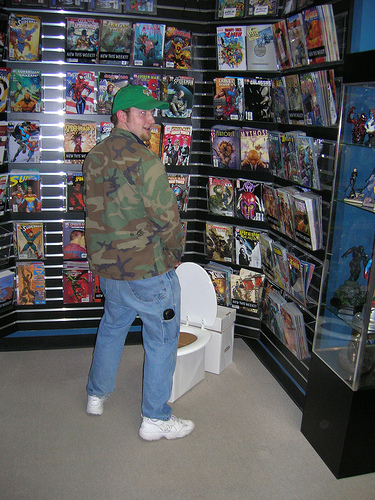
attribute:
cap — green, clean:
[106, 79, 174, 114]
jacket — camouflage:
[39, 125, 206, 275]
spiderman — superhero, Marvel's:
[61, 265, 98, 303]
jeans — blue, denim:
[92, 261, 172, 423]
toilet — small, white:
[155, 261, 256, 405]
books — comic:
[252, 22, 349, 129]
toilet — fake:
[171, 261, 244, 403]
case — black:
[144, 305, 190, 337]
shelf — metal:
[39, 17, 64, 67]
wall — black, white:
[15, 4, 367, 347]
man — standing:
[83, 85, 195, 439]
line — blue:
[7, 324, 148, 336]